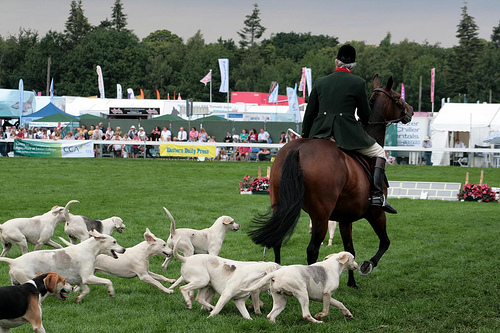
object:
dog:
[0, 205, 65, 257]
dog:
[58, 227, 176, 295]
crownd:
[1, 126, 274, 161]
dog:
[173, 236, 277, 319]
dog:
[239, 250, 358, 323]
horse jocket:
[3, 42, 418, 318]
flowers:
[239, 175, 261, 191]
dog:
[64, 199, 127, 244]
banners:
[12, 138, 94, 158]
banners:
[159, 144, 214, 156]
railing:
[0, 140, 271, 160]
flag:
[200, 69, 213, 84]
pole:
[209, 85, 212, 103]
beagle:
[0, 271, 73, 333]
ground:
[1, 155, 499, 333]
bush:
[458, 183, 495, 203]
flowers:
[457, 181, 493, 201]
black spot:
[83, 216, 103, 232]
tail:
[246, 150, 307, 251]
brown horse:
[242, 73, 414, 286]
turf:
[5, 157, 499, 329]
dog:
[159, 207, 240, 268]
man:
[302, 43, 398, 216]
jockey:
[296, 44, 413, 213]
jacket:
[299, 68, 376, 150]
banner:
[159, 143, 217, 158]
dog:
[0, 228, 125, 302]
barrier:
[0, 138, 499, 158]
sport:
[9, 44, 451, 201]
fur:
[114, 253, 147, 271]